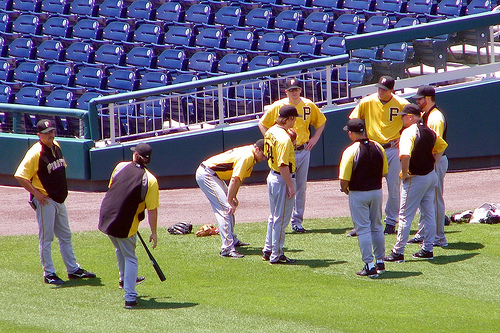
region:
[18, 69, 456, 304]
Nine pirates on a field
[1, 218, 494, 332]
rich green grass in the baseball park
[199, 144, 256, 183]
yellos jersey with a black side stripe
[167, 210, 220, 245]
a black baseball catchers mitt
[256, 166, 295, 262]
baseball pants with yellow side stripe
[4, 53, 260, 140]
heavy metal railings to separate fan seating from field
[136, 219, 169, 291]
a black baseball bat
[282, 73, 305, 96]
black baseball cap with yellow P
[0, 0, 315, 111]
blue stadium seating for fans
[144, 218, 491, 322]
players cast shadows on the ground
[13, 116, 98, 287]
man in black and yellow baseball shirt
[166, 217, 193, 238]
black baseball glove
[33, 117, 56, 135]
black baseball cap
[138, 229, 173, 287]
black baseball bat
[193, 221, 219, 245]
brown baseball glove lying on ground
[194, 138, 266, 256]
man in yellow shirt bent over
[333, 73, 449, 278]
group of men standing together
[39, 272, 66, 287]
black and white shoe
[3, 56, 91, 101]
blue stadium seats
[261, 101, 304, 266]
man standing on edge of baseball field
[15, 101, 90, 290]
man in black and yellow shirt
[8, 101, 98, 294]
man wearing black hat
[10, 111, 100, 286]
man wearing black tennis shoes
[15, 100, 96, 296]
man with moustache wearing sunglasses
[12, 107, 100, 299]
man wearing white baseball pants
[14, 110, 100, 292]
man in baseball attire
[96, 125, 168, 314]
man holding a baseball bat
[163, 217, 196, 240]
black catcher's mitt lying on the ground.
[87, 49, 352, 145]
blue and white metal railing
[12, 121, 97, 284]
this is a cricket player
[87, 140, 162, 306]
this is a cricket player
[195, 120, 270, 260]
this is a cricket player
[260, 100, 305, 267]
this is a cricket player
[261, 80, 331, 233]
this is a cricket player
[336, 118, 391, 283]
this is a cricket player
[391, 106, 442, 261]
this is a cricket player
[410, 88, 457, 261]
this is a cricket player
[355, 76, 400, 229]
this is a cricket player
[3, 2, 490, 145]
the chair are not occupied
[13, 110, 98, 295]
baseball player on a field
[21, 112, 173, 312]
two baseball player on a field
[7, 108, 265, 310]
three baseball players on the field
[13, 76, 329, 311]
five baseball players on the field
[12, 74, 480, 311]
eight baseball players on a field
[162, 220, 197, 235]
black baseball glove on a field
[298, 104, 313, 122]
p logo on the player's jersey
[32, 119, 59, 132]
dark colored hat on the player's head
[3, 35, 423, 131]
blue seats in a baseball stand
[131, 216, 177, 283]
black baseball bat in the player's hand